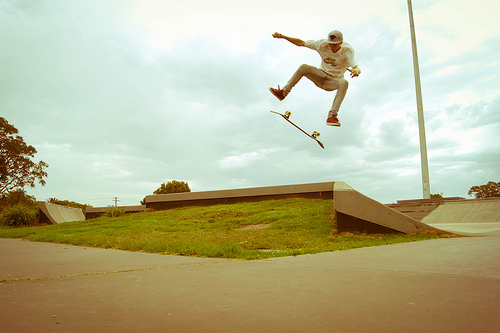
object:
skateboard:
[270, 106, 325, 150]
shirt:
[303, 39, 360, 78]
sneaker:
[268, 87, 286, 101]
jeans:
[300, 140, 366, 194]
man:
[268, 30, 360, 127]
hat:
[344, 106, 360, 121]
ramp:
[328, 182, 469, 237]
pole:
[403, 0, 432, 201]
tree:
[0, 117, 49, 204]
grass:
[0, 196, 452, 260]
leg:
[345, 153, 366, 194]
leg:
[299, 140, 343, 171]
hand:
[350, 66, 358, 78]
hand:
[289, 108, 300, 115]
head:
[345, 107, 360, 129]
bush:
[0, 204, 40, 229]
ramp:
[42, 201, 88, 224]